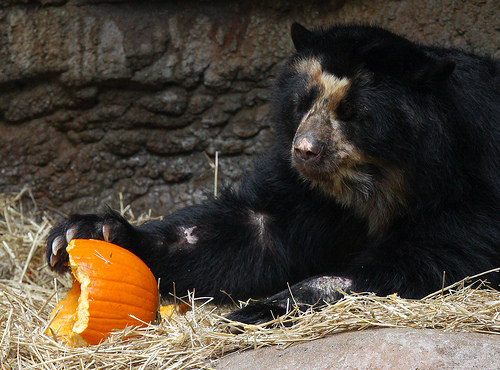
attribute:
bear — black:
[58, 26, 468, 318]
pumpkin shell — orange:
[36, 225, 186, 363]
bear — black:
[40, 23, 495, 310]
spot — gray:
[221, 277, 356, 334]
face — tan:
[281, 57, 401, 189]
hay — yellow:
[361, 289, 498, 325]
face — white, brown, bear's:
[282, 20, 460, 207]